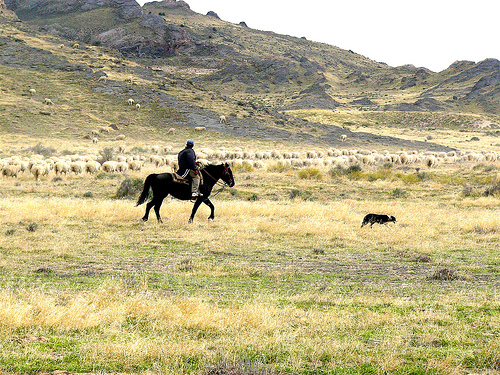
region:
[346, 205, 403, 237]
dog on the field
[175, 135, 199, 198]
person on the horse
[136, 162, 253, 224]
horse on the plains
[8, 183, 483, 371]
green and brown grass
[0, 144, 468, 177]
animals in a herd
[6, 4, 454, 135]
elevated terrain on plains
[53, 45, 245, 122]
animals on elevated terrain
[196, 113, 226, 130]
dirt on elevated terrain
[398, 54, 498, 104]
slopes on the terrain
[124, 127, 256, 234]
man is riding the horse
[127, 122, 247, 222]
man is riding the horse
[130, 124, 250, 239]
man is riding the horse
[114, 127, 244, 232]
man is riding the horse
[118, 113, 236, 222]
man is riding the horse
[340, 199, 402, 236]
a dog in the field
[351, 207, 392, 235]
a dog in the field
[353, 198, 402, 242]
a dog in the field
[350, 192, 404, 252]
a dog in the field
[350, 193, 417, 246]
a dog in the field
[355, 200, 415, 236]
this is a dog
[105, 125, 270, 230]
a man horseriding in a field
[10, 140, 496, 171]
this is a large herd of sheep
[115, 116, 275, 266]
the sheep herder is on a horse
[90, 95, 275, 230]
the man is riding his horse in dry grass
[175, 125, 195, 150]
he is wearing a blue hat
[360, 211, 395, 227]
Dog is in front of horse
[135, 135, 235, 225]
Horse is behind the dog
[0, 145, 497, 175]
Sheep are beside the horse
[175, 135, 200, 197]
Man is on the horse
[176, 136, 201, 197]
Man is wearing a hat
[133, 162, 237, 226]
Horse is beside the sheep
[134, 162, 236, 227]
The horse is black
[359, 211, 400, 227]
The dog is beside the sheep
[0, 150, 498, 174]
Sheep are beside the dog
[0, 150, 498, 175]
The sheep are next to a mountain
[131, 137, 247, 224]
Man on a horse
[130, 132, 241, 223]
Man is on a horse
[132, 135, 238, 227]
Man on a black horse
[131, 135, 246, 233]
Man is on a black horse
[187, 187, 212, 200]
Man wearing white shoes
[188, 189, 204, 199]
Man is wearing white shoes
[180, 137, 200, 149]
Man wearing a blue hat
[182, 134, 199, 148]
Man is wearing a blue hat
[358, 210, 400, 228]
Black and white dog walking on the grass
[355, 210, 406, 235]
Black and white dog is walking on the grass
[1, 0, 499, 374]
the man on the horse in a large opened area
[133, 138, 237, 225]
the man riding the horse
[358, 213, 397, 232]
the dog is walking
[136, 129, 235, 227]
man riding dark horse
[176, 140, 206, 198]
man in blue shirt and blue cap riding horse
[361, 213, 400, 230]
dog in field in front of horse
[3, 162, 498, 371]
large grassy plain with horse and dog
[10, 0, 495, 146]
mountain range in distance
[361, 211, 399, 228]
dog with white collar of fur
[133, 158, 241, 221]
dark horse with red reins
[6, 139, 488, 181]
white fluffy sheep in pasture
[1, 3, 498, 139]
grassy mountain range in distance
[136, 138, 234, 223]
man is riding a horse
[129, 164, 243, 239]
horse is walking in the field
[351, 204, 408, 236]
dog is walking in the field